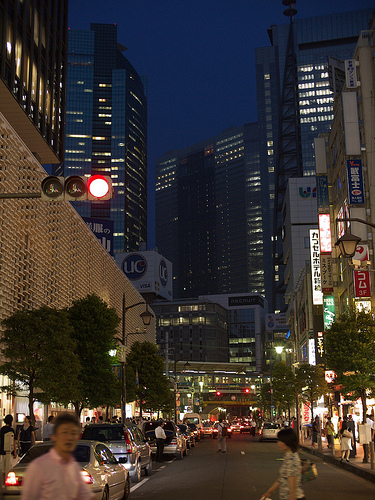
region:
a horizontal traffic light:
[4, 165, 117, 204]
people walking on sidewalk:
[297, 403, 370, 471]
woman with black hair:
[255, 420, 323, 498]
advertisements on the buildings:
[304, 199, 370, 321]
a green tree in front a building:
[321, 297, 374, 474]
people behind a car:
[143, 415, 186, 461]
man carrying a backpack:
[212, 411, 235, 458]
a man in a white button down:
[23, 409, 91, 497]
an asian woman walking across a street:
[261, 427, 317, 497]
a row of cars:
[0, 409, 201, 493]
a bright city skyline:
[8, 14, 371, 338]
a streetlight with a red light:
[21, 159, 119, 211]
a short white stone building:
[166, 350, 282, 431]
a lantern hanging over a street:
[325, 213, 373, 265]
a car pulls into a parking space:
[6, 440, 133, 497]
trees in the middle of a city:
[9, 293, 183, 410]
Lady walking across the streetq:
[255, 425, 323, 497]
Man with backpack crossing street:
[209, 417, 235, 456]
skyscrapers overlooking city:
[37, 40, 358, 295]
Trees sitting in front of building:
[9, 283, 191, 421]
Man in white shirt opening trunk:
[151, 422, 169, 460]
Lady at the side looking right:
[333, 423, 358, 464]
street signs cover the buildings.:
[276, 164, 370, 437]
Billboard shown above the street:
[107, 242, 184, 304]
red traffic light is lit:
[38, 175, 113, 201]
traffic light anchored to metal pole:
[0, 159, 111, 195]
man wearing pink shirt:
[18, 411, 93, 495]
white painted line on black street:
[129, 428, 370, 495]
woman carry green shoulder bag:
[256, 426, 317, 495]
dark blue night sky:
[63, 0, 370, 251]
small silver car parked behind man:
[1, 410, 125, 496]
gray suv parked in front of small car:
[3, 417, 153, 494]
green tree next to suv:
[0, 302, 86, 433]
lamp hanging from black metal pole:
[120, 291, 153, 423]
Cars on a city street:
[4, 407, 285, 498]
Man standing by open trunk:
[141, 414, 184, 460]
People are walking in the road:
[24, 407, 332, 499]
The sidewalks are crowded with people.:
[270, 402, 373, 464]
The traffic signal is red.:
[8, 163, 119, 209]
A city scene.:
[1, 5, 374, 494]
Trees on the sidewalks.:
[8, 295, 374, 459]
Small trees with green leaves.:
[7, 288, 372, 458]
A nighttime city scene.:
[3, 7, 372, 498]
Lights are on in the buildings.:
[6, 6, 374, 406]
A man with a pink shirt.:
[19, 413, 89, 499]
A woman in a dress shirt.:
[256, 423, 314, 499]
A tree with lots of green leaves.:
[2, 294, 121, 428]